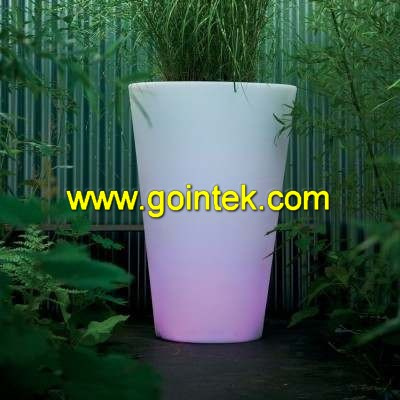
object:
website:
[66, 183, 330, 219]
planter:
[126, 79, 299, 344]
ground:
[63, 317, 400, 399]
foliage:
[44, 0, 294, 83]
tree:
[274, 0, 400, 230]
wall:
[0, 0, 400, 314]